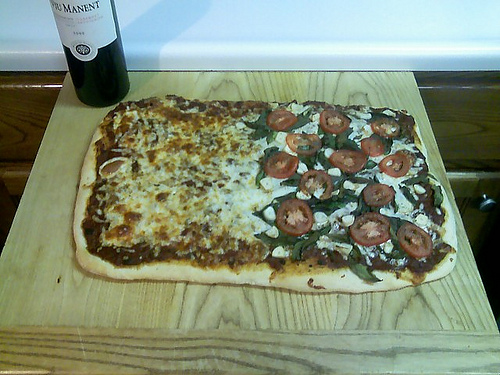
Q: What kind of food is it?
A: Pizza.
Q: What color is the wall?
A: White.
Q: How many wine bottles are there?
A: One.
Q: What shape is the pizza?
A: Rectangle.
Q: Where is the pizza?
A: On a table.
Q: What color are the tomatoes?
A: Red.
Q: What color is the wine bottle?
A: Green.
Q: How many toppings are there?
A: Four.